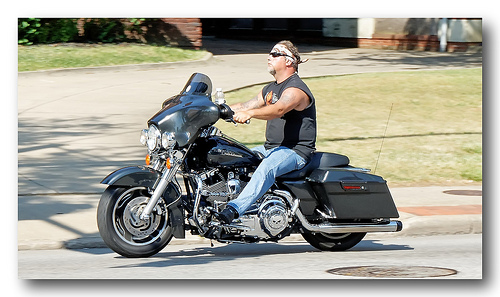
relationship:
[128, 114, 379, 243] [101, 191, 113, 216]
motorcycle has tire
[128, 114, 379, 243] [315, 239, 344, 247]
motorcycle has tire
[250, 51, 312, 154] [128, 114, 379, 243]
man on motorcycle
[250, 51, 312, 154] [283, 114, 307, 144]
man has shirt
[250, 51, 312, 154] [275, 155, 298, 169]
man has pants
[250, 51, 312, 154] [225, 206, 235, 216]
man has shoe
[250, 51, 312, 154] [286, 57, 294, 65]
man has ear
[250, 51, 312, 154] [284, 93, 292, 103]
man has tattoo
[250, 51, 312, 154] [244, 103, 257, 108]
man has tattoo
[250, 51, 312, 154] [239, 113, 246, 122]
man has hand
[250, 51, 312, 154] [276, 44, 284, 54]
man has durag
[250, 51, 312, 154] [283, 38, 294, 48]
man has hair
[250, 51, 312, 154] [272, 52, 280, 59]
man has glasses